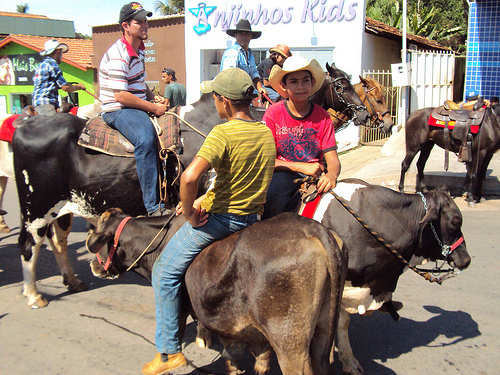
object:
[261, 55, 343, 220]
boy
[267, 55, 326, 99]
cowboy hat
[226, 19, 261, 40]
cowboy hat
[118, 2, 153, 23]
baseball cap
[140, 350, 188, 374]
boot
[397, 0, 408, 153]
pole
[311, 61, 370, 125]
horse's head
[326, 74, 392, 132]
horse's head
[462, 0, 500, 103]
wall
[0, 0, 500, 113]
building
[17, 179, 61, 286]
right leg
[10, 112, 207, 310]
cow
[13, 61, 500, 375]
cows and horses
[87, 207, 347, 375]
cow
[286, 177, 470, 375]
cow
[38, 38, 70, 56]
cowboy hat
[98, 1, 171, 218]
man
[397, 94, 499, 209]
horse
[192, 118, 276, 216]
shirt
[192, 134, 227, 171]
short sleeves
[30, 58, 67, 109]
shirt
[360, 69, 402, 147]
fence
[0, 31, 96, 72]
roof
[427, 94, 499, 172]
saddle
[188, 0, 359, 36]
business name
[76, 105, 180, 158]
harness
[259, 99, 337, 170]
shirt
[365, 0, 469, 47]
trees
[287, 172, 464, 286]
bridle